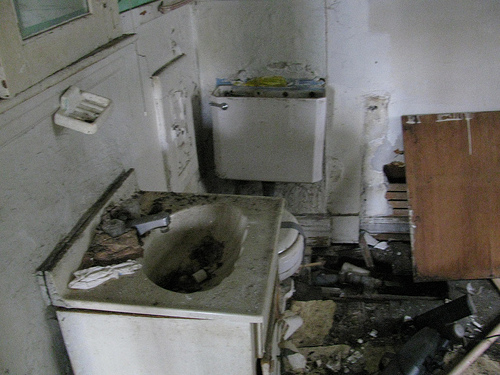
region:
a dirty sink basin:
[128, 195, 250, 315]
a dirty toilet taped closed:
[266, 193, 317, 292]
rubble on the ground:
[313, 284, 440, 371]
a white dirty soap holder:
[52, 81, 121, 144]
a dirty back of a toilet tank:
[200, 73, 344, 190]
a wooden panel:
[389, 97, 491, 288]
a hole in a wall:
[354, 123, 414, 233]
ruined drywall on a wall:
[358, 79, 398, 224]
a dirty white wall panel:
[152, 59, 195, 191]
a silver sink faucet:
[132, 211, 177, 242]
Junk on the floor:
[146, 75, 466, 370]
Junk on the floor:
[330, 280, 412, 351]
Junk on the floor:
[431, 281, 490, 351]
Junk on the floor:
[318, 238, 363, 282]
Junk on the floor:
[304, 338, 339, 358]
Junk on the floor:
[403, 351, 438, 371]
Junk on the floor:
[454, 277, 484, 310]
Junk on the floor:
[364, 235, 394, 267]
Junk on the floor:
[338, 346, 380, 371]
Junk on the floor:
[319, 268, 340, 292]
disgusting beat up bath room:
[33, 28, 450, 355]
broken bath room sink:
[62, 190, 295, 333]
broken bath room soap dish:
[49, 73, 122, 145]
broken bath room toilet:
[201, 70, 339, 272]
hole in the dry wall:
[363, 88, 425, 261]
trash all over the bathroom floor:
[303, 265, 479, 371]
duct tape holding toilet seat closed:
[273, 205, 319, 250]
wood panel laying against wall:
[396, 112, 498, 294]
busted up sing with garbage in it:
[56, 190, 293, 329]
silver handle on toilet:
[202, 92, 237, 126]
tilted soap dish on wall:
[55, 83, 113, 137]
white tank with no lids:
[209, 81, 327, 182]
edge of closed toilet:
[277, 207, 304, 279]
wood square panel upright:
[399, 111, 499, 281]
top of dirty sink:
[42, 168, 287, 321]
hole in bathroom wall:
[378, 158, 408, 215]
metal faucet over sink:
[133, 211, 173, 238]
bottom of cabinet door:
[0, 1, 122, 91]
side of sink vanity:
[57, 311, 257, 373]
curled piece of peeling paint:
[267, 294, 304, 370]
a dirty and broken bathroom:
[9, 5, 499, 372]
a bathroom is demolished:
[14, 13, 496, 374]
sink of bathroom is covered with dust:
[54, 165, 286, 333]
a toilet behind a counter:
[204, 184, 311, 303]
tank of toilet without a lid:
[201, 75, 334, 196]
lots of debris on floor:
[279, 223, 489, 374]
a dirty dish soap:
[50, 79, 121, 141]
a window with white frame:
[1, 2, 198, 113]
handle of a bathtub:
[204, 98, 231, 113]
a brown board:
[391, 103, 498, 289]